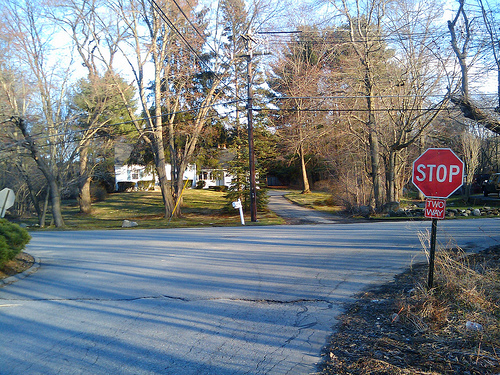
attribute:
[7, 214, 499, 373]
intersection — pictured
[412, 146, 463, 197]
stop sign — pictured, red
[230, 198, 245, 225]
mailbox — residential, white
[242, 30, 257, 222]
telephone — pictured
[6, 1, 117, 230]
tree — leaveless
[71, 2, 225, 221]
tree — leaveless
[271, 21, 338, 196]
tree — leaveless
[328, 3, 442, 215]
tree — leaveless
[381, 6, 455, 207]
tree — leaveless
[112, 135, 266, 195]
house — white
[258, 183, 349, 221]
driveway — pictured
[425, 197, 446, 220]
sign — two way stop, two way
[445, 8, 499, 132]
branch — large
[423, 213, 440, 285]
pole — metal